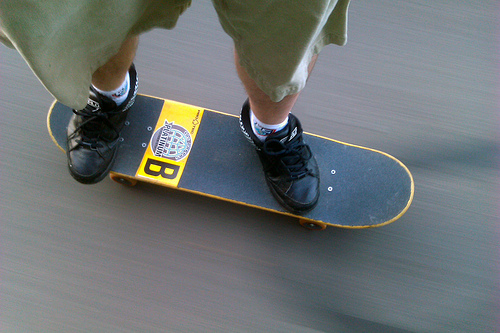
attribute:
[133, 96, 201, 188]
stripe — bright yellow, yellow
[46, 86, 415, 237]
skateboard — black, moving, part, short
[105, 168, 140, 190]
wheel — orange, bright orange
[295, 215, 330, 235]
wheel — orange, bright orange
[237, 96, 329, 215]
tennis shoe — black, part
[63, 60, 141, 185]
tennis shoe — black, part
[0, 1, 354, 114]
shorts — khaki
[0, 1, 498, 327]
ground — part, blurry, dark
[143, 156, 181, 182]
letter — capital b, b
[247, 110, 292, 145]
ankle sock — white, cotton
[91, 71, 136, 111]
ankle sock — cotton, white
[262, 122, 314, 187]
shoe lace — part, black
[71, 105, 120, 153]
shoe lace — black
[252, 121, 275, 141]
design — red, blue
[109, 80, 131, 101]
design — red, blue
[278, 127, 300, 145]
lettering — white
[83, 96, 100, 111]
lettering — white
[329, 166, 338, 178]
grommet — silver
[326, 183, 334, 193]
grommet — silver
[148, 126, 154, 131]
grommet — silver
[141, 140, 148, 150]
grommet — silver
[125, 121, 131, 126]
grommet — silver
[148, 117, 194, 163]
label — part